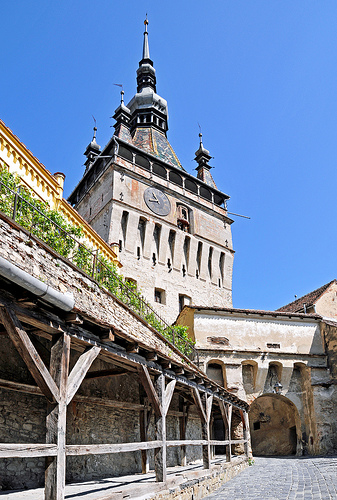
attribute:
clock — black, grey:
[141, 181, 177, 220]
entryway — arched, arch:
[239, 384, 312, 464]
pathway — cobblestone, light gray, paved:
[238, 448, 336, 499]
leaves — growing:
[1, 172, 201, 361]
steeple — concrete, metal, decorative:
[97, 10, 202, 173]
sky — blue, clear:
[231, 5, 336, 268]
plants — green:
[2, 176, 118, 267]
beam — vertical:
[1, 302, 107, 499]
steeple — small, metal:
[191, 122, 221, 188]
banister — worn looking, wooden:
[147, 158, 157, 175]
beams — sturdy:
[112, 134, 233, 203]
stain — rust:
[127, 172, 144, 201]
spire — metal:
[108, 79, 136, 142]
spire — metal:
[79, 115, 107, 169]